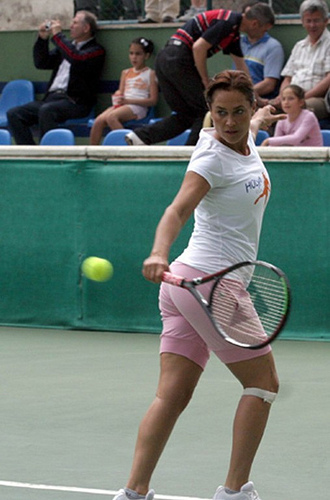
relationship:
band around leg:
[240, 386, 277, 404] [172, 265, 282, 498]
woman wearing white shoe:
[110, 68, 287, 500] [209, 479, 264, 498]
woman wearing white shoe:
[110, 68, 287, 500] [105, 487, 157, 499]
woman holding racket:
[110, 68, 287, 500] [161, 259, 292, 350]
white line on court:
[1, 471, 211, 498] [1, 327, 328, 498]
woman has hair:
[110, 68, 287, 500] [199, 68, 259, 103]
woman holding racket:
[117, 65, 288, 431] [138, 247, 296, 326]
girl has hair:
[106, 31, 178, 143] [130, 36, 154, 54]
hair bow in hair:
[138, 38, 148, 48] [130, 36, 154, 54]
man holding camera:
[8, 9, 105, 144] [39, 17, 65, 39]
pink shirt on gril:
[268, 109, 323, 146] [277, 83, 324, 151]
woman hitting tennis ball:
[110, 68, 287, 500] [76, 255, 125, 287]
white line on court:
[0, 479, 205, 500] [0, 322, 330, 499]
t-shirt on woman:
[174, 129, 272, 284] [110, 68, 287, 500]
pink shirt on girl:
[271, 114, 322, 145] [273, 84, 322, 147]